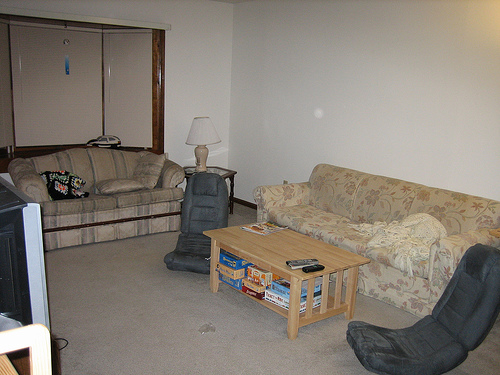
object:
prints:
[362, 189, 380, 206]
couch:
[8, 147, 185, 253]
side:
[0, 196, 29, 324]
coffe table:
[202, 221, 371, 338]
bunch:
[215, 247, 322, 315]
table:
[200, 221, 372, 339]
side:
[151, 29, 164, 151]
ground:
[43, 196, 500, 375]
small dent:
[311, 108, 323, 122]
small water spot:
[195, 324, 218, 334]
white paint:
[3, 1, 499, 213]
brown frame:
[0, 12, 166, 155]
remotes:
[284, 258, 318, 270]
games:
[268, 278, 324, 300]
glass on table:
[183, 167, 231, 177]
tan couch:
[254, 162, 500, 319]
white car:
[85, 135, 121, 146]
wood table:
[182, 165, 235, 216]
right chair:
[163, 172, 228, 275]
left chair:
[346, 242, 500, 374]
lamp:
[186, 115, 222, 172]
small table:
[180, 165, 237, 215]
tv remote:
[300, 264, 325, 273]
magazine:
[241, 222, 290, 236]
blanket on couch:
[347, 211, 448, 276]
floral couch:
[251, 164, 498, 353]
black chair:
[346, 242, 499, 374]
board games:
[218, 247, 253, 269]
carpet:
[42, 196, 499, 375]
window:
[8, 25, 104, 147]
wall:
[2, 0, 499, 211]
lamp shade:
[184, 115, 221, 144]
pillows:
[93, 178, 145, 196]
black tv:
[0, 174, 51, 335]